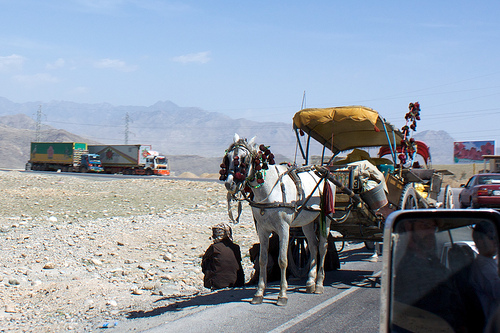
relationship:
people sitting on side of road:
[151, 117, 384, 292] [121, 175, 428, 303]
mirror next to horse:
[377, 205, 498, 332] [221, 134, 334, 314]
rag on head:
[214, 222, 232, 240] [214, 223, 232, 243]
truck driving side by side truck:
[27, 137, 104, 174] [86, 142, 171, 177]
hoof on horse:
[243, 287, 280, 307] [217, 135, 340, 304]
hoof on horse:
[279, 285, 290, 310] [217, 135, 340, 304]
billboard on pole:
[451, 137, 498, 167] [23, 97, 143, 151]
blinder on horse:
[237, 154, 249, 179] [221, 134, 334, 314]